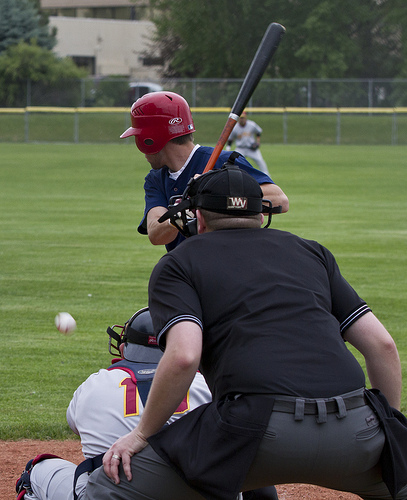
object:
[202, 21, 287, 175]
bat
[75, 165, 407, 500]
umpire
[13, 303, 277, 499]
catcher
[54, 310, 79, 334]
baseball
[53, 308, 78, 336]
stitching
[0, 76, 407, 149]
fence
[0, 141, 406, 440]
grass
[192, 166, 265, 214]
cap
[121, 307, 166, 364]
helmet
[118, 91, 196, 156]
helmet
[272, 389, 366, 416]
belt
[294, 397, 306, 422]
loops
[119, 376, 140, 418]
number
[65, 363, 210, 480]
jersey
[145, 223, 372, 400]
shirt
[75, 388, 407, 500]
pants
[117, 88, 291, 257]
man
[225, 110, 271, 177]
player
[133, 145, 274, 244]
top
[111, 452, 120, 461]
ring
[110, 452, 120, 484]
finger